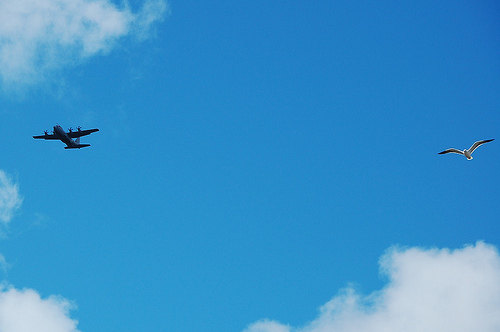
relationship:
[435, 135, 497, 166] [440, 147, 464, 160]
seagull has wing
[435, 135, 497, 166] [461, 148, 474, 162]
seagull has body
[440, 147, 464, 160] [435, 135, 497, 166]
wing extended from seagull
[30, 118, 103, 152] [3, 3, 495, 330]
airplane in sky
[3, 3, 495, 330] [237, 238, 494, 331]
sky behind cloud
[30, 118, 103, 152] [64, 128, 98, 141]
airplane has wing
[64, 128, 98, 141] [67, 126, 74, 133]
wing has prop engine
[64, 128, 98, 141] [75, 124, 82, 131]
wing has prop engine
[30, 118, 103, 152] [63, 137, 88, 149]
airplane has tail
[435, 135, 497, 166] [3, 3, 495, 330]
seagull soaring in sky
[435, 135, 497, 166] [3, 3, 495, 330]
seagull flying in sky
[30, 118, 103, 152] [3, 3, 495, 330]
airplane flying in sky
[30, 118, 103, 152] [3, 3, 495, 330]
airplane soaring in sky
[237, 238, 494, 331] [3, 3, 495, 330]
cloud in sky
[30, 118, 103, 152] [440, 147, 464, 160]
airplane has wing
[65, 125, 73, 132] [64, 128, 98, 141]
propeller on side of wing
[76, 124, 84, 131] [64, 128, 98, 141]
propeller on side of wing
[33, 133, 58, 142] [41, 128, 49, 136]
wing has propeller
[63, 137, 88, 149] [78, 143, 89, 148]
tail has wing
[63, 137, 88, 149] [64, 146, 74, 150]
tail has wing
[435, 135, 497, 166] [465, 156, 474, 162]
seagull has tail feathers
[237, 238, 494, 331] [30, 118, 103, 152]
cloud under airplane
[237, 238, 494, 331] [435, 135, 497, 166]
cloud under seagull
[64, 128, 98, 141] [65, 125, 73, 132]
wing has propeller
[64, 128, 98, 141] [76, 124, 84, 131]
wing has propeller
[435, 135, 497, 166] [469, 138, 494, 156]
seagull has wing